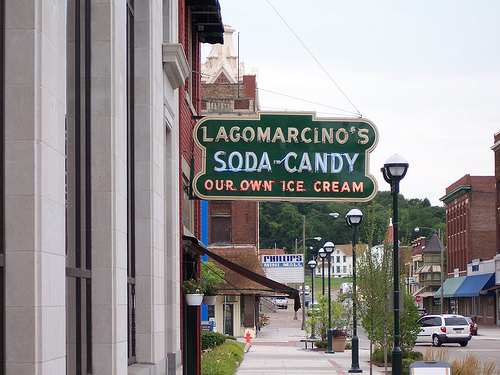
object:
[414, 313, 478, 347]
car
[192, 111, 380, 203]
sign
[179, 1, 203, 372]
store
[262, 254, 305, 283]
sign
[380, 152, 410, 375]
light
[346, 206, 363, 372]
light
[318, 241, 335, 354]
light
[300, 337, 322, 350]
bench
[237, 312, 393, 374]
sidewalk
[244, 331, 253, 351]
fire hydrant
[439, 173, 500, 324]
building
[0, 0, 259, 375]
building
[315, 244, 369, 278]
house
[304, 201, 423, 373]
tree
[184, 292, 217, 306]
pot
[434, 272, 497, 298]
canopies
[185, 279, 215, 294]
flowers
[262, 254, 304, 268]
word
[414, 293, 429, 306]
sign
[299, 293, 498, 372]
road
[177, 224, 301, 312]
awning